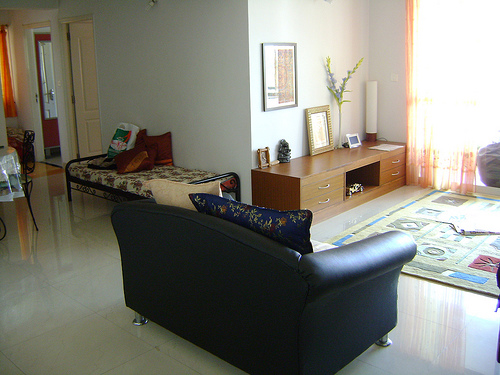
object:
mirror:
[262, 42, 299, 112]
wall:
[246, 0, 407, 171]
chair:
[0, 131, 39, 232]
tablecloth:
[0, 146, 28, 261]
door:
[64, 20, 102, 159]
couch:
[109, 193, 416, 374]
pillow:
[187, 192, 313, 255]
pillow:
[142, 179, 223, 212]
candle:
[365, 82, 377, 134]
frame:
[306, 105, 335, 156]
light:
[396, 235, 415, 246]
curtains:
[405, 0, 477, 194]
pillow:
[114, 144, 158, 174]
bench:
[64, 152, 241, 203]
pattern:
[257, 214, 287, 230]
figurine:
[277, 139, 291, 163]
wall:
[92, 0, 251, 206]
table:
[251, 141, 407, 227]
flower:
[324, 55, 364, 149]